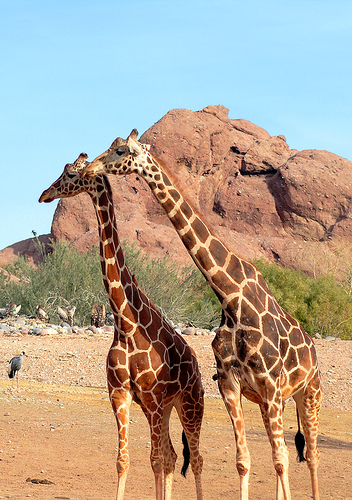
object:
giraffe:
[36, 152, 204, 499]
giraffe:
[88, 126, 324, 499]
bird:
[7, 349, 31, 391]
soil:
[6, 391, 108, 499]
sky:
[0, 0, 352, 105]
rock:
[184, 116, 351, 196]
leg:
[219, 379, 260, 500]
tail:
[292, 404, 311, 465]